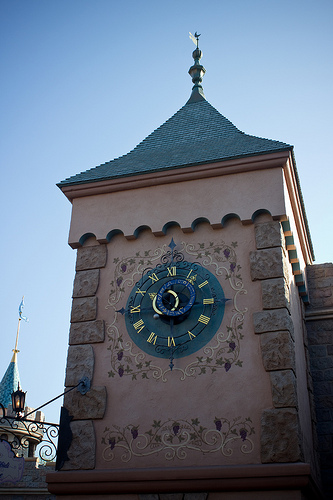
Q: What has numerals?
A: The clock.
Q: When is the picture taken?
A: Daytime.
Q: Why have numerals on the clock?
A: To tell the time.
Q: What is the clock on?
A: A building.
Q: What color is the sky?
A: Blue.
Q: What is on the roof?
A: A weather vane.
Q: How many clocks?
A: One.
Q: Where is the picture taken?
A: At the base of a clock tower.